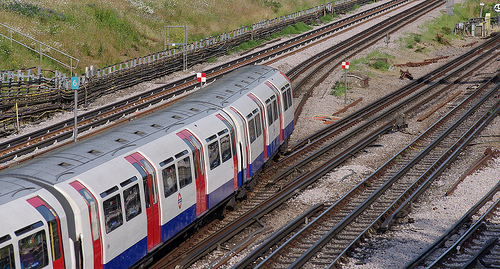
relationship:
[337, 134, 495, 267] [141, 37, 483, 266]
gravel between tracks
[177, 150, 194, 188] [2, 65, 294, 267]
window on train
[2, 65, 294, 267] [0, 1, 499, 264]
train on tracks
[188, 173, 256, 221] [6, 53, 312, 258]
stripe on train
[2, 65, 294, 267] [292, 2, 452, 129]
train driving along tracks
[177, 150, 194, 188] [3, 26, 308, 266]
window on train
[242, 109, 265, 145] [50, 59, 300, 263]
square window on train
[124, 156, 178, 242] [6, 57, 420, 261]
door on side of train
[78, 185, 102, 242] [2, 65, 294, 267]
window on side train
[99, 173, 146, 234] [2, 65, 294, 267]
windows on train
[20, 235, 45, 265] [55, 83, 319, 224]
window on train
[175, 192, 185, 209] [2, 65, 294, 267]
logo on side of train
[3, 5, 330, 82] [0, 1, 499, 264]
grass growing on hill behind tracks